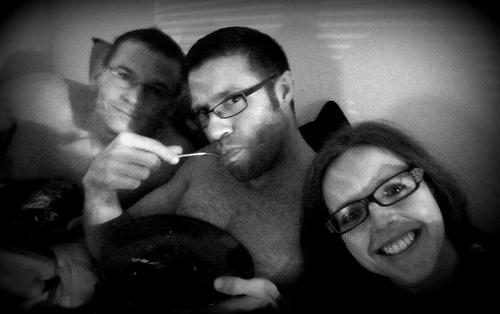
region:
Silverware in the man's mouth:
[179, 150, 219, 157]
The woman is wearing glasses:
[326, 165, 423, 235]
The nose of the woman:
[370, 202, 392, 229]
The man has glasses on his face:
[189, 70, 278, 130]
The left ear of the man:
[278, 70, 291, 100]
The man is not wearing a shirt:
[180, 145, 310, 278]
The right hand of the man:
[81, 133, 183, 188]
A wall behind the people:
[0, 1, 498, 231]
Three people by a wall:
[1, 28, 496, 313]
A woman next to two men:
[302, 123, 498, 313]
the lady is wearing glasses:
[332, 182, 409, 214]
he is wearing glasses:
[200, 100, 247, 120]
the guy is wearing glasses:
[118, 69, 160, 104]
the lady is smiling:
[378, 225, 422, 259]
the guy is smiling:
[113, 103, 138, 124]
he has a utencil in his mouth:
[197, 145, 235, 162]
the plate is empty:
[149, 241, 191, 281]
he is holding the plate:
[203, 264, 248, 310]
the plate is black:
[183, 230, 213, 256]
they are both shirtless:
[42, 93, 279, 213]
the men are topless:
[6, 24, 341, 311]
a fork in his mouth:
[136, 121, 286, 186]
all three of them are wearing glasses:
[24, 7, 478, 304]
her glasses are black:
[311, 149, 461, 247]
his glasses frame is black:
[156, 58, 313, 155]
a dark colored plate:
[88, 182, 294, 306]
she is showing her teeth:
[301, 81, 489, 311]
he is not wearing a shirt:
[77, 4, 332, 313]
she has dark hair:
[292, 89, 491, 313]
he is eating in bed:
[81, 11, 351, 312]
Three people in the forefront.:
[0, 19, 481, 311]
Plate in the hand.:
[92, 201, 264, 310]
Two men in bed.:
[0, 16, 322, 308]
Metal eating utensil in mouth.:
[162, 136, 239, 167]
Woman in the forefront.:
[291, 115, 498, 308]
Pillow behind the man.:
[295, 88, 353, 158]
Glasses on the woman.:
[297, 112, 430, 248]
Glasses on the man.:
[181, 65, 295, 136]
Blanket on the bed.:
[10, 239, 96, 307]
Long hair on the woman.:
[286, 107, 488, 307]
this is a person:
[304, 125, 463, 305]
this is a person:
[71, 39, 328, 291]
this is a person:
[11, 28, 194, 308]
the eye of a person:
[109, 63, 138, 96]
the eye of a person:
[146, 77, 168, 116]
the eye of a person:
[215, 89, 241, 127]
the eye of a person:
[187, 93, 219, 133]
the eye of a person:
[336, 193, 366, 238]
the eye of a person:
[369, 180, 418, 213]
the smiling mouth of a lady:
[367, 228, 423, 265]